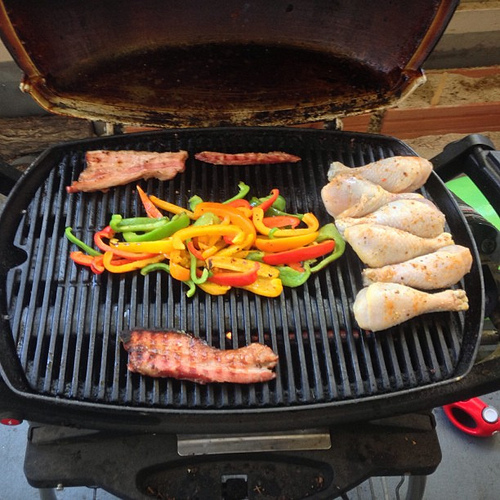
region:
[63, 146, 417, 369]
Food cooking on the grill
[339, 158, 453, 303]
Chicken drumsticks are cooking on the grill.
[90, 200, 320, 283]
Peppers are cooking on the grill.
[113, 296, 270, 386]
A piece of meat grilling.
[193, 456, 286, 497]
Knob on the black grill.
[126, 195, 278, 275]
The peppers are green, yellow and red.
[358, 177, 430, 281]
The chicken has seasoning on top of it.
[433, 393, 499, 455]
A red object on the ground,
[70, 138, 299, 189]
Meat cooking on the back of the grill.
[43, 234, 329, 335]
The grill is made of iron.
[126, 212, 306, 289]
Three colors of peppers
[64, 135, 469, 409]
Dinner on the grill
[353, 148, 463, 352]
Six drumsticks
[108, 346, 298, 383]
Single piece of meat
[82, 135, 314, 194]
Two smaller pieces of meat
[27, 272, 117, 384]
A black grill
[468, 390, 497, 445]
Lighter for a grill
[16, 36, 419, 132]
Lid to a grill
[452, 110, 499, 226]
Plastic handle on right side of grill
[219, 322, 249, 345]
Flame under the food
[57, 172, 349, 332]
the peppers are colored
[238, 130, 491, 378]
chicken legs on a grill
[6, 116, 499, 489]
the grill is black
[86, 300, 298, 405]
a piece of a rib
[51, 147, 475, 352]
the chicken is beside the peppers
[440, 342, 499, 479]
a red item below the grill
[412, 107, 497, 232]
the grill handle is black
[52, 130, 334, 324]
two pieces of ribs above the peppers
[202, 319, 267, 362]
a small flame beneath the grill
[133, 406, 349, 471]
a silver handle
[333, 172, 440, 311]
Seasoning on the chicken.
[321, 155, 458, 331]
The chicken is raw.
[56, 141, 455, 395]
Food on a grill.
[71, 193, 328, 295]
Sliced peppers on the grill.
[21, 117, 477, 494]
The grill is black.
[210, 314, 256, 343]
Flame in the grill.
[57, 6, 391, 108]
Rust in the hood.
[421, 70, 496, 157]
Dirt on the steps.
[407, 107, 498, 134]
The step is brown.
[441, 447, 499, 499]
The ground is grey.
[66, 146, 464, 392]
the food is on a grill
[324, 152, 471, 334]
the chicken legs are raw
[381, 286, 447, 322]
the chicken leg is seasoned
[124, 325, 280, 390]
the meat has been grilled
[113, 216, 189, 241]
the food is green in color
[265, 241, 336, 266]
the food is red in color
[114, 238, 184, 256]
the food is yellow in color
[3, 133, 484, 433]
the grill is black in color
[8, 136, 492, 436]
the grill is made of metal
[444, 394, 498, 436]
the igniter is red in color